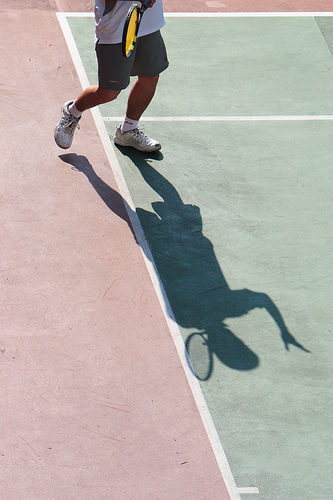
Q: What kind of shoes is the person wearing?
A: White tennis shoes.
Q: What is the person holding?
A: A tennis racquet.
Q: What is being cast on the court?
A: A shadow of the player.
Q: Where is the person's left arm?
A: Up in the air.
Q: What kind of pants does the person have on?
A: Shorts.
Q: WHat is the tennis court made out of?
A: Clay.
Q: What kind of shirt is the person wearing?
A: A white tennis shirt.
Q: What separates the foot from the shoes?
A: White socks.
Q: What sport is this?
A: Tennis.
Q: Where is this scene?
A: Tennis court.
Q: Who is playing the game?
A: A man.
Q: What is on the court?
A: Shadow.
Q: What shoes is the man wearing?
A: Sneakers.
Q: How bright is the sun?
A: Very bright.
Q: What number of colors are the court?
A: 2.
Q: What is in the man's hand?
A: Racket.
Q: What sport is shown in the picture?
A: Tennis.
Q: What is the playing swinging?
A: Racket.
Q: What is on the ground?
A: Shadow.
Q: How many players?
A: 1.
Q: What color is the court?
A: Green.